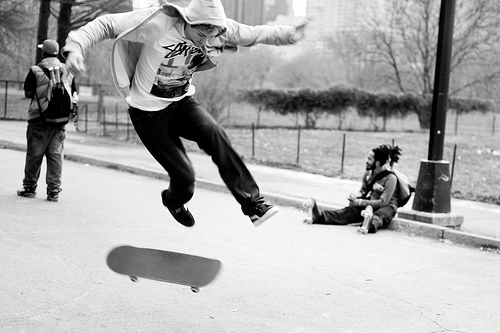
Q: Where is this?
A: This is at the park.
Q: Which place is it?
A: It is a park.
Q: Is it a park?
A: Yes, it is a park.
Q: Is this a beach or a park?
A: It is a park.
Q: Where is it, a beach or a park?
A: It is a park.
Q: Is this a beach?
A: No, it is a park.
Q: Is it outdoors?
A: Yes, it is outdoors.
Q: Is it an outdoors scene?
A: Yes, it is outdoors.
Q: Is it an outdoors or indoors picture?
A: It is outdoors.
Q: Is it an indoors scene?
A: No, it is outdoors.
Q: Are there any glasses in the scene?
A: No, there are no glasses.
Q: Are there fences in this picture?
A: Yes, there is a fence.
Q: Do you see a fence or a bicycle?
A: Yes, there is a fence.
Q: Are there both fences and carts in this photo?
A: No, there is a fence but no carts.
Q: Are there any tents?
A: No, there are no tents.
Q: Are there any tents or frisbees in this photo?
A: No, there are no tents or frisbees.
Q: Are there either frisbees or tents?
A: No, there are no tents or frisbees.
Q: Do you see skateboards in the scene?
A: Yes, there is a skateboard.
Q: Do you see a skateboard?
A: Yes, there is a skateboard.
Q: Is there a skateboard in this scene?
A: Yes, there is a skateboard.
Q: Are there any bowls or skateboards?
A: Yes, there is a skateboard.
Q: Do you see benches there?
A: No, there are no benches.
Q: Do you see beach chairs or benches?
A: No, there are no benches or beach chairs.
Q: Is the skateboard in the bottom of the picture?
A: Yes, the skateboard is in the bottom of the image.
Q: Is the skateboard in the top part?
A: No, the skateboard is in the bottom of the image.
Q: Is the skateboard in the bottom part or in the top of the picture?
A: The skateboard is in the bottom of the image.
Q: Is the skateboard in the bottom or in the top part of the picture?
A: The skateboard is in the bottom of the image.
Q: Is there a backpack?
A: Yes, there is a backpack.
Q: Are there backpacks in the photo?
A: Yes, there is a backpack.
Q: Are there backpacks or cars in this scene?
A: Yes, there is a backpack.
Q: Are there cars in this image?
A: No, there are no cars.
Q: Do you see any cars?
A: No, there are no cars.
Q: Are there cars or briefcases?
A: No, there are no cars or briefcases.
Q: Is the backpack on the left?
A: Yes, the backpack is on the left of the image.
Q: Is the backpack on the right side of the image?
A: No, the backpack is on the left of the image.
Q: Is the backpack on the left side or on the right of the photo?
A: The backpack is on the left of the image.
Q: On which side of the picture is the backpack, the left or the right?
A: The backpack is on the left of the image.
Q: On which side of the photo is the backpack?
A: The backpack is on the left of the image.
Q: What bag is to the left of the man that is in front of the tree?
A: The bag is a backpack.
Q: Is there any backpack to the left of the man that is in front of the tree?
A: Yes, there is a backpack to the left of the man.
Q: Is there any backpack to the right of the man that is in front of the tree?
A: No, the backpack is to the left of the man.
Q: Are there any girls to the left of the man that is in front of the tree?
A: No, there is a backpack to the left of the man.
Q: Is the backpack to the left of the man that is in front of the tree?
A: Yes, the backpack is to the left of the man.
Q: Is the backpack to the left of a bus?
A: No, the backpack is to the left of the man.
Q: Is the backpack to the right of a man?
A: No, the backpack is to the left of a man.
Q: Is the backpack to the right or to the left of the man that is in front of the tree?
A: The backpack is to the left of the man.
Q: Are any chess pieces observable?
A: No, there are no chess pieces.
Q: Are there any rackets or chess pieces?
A: No, there are no chess pieces or rackets.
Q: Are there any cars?
A: No, there are no cars.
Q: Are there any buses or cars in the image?
A: No, there are no cars or buses.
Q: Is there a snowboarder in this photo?
A: No, there are no snowboarders.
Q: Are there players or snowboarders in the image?
A: No, there are no snowboarders or players.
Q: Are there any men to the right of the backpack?
A: Yes, there is a man to the right of the backpack.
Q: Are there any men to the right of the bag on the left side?
A: Yes, there is a man to the right of the backpack.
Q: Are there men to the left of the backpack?
A: No, the man is to the right of the backpack.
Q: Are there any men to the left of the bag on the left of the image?
A: No, the man is to the right of the backpack.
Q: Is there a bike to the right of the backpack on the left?
A: No, there is a man to the right of the backpack.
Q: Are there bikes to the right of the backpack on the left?
A: No, there is a man to the right of the backpack.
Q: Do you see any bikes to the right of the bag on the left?
A: No, there is a man to the right of the backpack.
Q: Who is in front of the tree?
A: The man is in front of the tree.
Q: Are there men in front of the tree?
A: Yes, there is a man in front of the tree.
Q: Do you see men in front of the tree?
A: Yes, there is a man in front of the tree.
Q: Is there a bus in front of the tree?
A: No, there is a man in front of the tree.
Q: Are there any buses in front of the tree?
A: No, there is a man in front of the tree.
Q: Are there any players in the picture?
A: No, there are no players.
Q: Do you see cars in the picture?
A: No, there are no cars.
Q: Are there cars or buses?
A: No, there are no cars or buses.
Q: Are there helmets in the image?
A: No, there are no helmets.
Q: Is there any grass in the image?
A: Yes, there is grass.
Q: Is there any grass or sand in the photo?
A: Yes, there is grass.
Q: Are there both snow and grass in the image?
A: No, there is grass but no snow.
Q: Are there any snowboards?
A: No, there are no snowboards.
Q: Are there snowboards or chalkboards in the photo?
A: No, there are no snowboards or chalkboards.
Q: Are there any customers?
A: No, there are no customers.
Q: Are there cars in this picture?
A: No, there are no cars.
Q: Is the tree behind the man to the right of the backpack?
A: Yes, the tree is behind the man.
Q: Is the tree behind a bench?
A: No, the tree is behind the man.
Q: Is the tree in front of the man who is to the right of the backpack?
A: No, the tree is behind the man.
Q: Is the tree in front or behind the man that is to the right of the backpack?
A: The tree is behind the man.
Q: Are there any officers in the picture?
A: No, there are no officers.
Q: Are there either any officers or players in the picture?
A: No, there are no officers or players.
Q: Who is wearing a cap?
A: The man is wearing a cap.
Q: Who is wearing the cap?
A: The man is wearing a cap.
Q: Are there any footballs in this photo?
A: No, there are no footballs.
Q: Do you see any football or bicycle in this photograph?
A: No, there are no footballs or bicycles.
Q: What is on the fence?
A: The vines are on the fence.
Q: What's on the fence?
A: The vines are on the fence.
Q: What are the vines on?
A: The vines are on the fence.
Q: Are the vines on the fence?
A: Yes, the vines are on the fence.